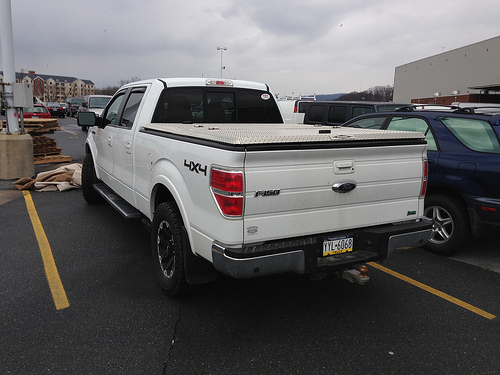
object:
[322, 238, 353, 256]
plate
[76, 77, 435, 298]
truck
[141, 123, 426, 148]
cover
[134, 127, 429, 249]
bed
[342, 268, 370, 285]
hitch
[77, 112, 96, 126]
mirror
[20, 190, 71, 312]
lines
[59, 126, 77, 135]
lines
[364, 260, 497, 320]
lines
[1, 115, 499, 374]
street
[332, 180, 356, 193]
emblem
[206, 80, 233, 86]
light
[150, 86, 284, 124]
window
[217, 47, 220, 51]
lighting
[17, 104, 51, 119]
car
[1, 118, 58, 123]
pallets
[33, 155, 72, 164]
pallets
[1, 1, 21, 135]
pole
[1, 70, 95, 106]
complex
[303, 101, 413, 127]
van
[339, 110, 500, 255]
car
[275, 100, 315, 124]
van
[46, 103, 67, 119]
car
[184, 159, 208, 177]
4x4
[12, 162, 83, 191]
tarp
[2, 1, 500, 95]
sky